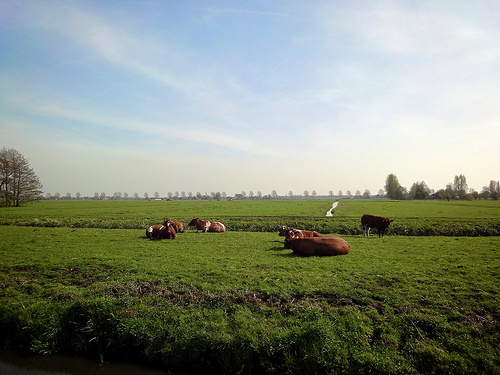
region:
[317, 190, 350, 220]
a small stream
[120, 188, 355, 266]
some cows laying down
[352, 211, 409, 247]
a cow standing up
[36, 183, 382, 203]
a row of young trees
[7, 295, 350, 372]
some tall green grass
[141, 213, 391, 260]
Seven cows in a field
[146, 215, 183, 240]
Two cows laying down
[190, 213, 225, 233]
One cow lying down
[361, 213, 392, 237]
One cow standing up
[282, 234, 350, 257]
The cow is brown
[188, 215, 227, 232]
The cow has white patches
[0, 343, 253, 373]
Water in the foreground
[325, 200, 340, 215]
A creek in background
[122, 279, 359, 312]
Brown patch in grass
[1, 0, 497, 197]
Sirus clouds in the sky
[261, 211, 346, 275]
brown cows in green field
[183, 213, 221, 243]
brown cows in green field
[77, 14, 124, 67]
white clouds in blue sky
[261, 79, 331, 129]
white clouds in blue sky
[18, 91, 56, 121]
white clouds in blue sky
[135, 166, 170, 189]
white clouds in blue sky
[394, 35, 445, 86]
white clouds in blue sky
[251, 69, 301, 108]
white clouds in blue sky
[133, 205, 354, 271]
brown cows in green field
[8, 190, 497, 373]
green grass field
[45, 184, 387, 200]
tall trees bordering green field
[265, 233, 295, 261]
shadows of cows on grass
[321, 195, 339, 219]
stream of water in between grass field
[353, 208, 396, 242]
one cow standing up in green field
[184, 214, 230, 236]
brown and white cow lying down in field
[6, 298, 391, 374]
black shadow in field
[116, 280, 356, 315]
dirt patch in green field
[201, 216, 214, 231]
white spot on brown cow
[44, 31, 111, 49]
white clouds in blue sky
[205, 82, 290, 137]
white clouds in blue sky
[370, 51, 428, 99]
white clouds in blue sky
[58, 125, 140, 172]
white clouds in blue sky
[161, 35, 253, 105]
white clouds in blue sky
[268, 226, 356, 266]
brown cows lying in green field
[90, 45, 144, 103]
white clouds in blue sky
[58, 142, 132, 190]
white clouds in blue sky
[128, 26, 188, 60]
white clouds in blue sky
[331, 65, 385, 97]
white clouds in blue sky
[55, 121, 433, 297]
this is an open field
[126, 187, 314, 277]
the cows are grouped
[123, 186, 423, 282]
the cows are laying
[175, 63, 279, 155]
a view of sky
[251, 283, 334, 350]
a view of grass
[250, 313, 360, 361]
a view of plants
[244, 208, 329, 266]
a view of animals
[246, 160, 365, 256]
a view of cow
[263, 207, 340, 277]
animal sitting in the grass